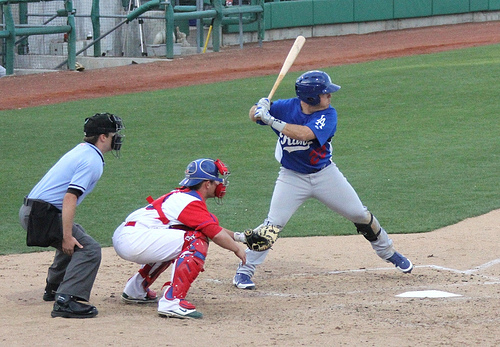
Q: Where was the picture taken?
A: On a baseball field.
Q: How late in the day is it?
A: Afternoon.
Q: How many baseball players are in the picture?
A: Two.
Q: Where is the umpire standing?
A: Behind the catcher.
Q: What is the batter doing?
A: Getting ready to swing.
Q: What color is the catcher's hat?
A: Blue.